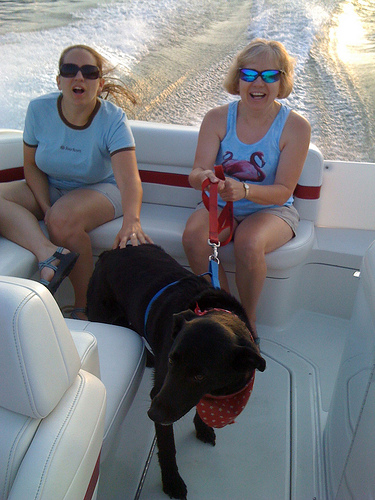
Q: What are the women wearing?
A: Blue shirt.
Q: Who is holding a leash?
A: Woman on right.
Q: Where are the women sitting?
A: In a boat.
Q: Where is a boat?
A: On the water.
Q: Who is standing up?
A: The dog.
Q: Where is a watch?
A: Around woman's wrist.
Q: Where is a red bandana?
A: Around dog's neck.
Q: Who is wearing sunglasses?
A: Both women.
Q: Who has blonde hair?
A: Lady on right.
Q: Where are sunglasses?
A: Over women's eyes.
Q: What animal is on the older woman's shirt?
A: Flamingo.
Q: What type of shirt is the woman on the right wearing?
A: Tank top.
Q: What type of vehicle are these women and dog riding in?
A: Speed boat.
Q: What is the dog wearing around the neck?
A: Bandana.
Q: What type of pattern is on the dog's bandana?
A: Red and white polka dots.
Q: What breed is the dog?
A: Black lab/shepherd mix.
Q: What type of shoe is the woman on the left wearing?
A: Sandals.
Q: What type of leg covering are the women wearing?
A: Short shorts.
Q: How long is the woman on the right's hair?
A: Just below her ears.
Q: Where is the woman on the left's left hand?
A: On the dog.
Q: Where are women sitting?
A: On a boat.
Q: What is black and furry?
A: Dog.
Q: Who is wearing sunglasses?
A: Both women.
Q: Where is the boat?
A: On the water.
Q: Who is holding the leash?
A: Woman on right.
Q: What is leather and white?
A: Boat seats.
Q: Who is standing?
A: The dog.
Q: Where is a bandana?
A: Around dog's neck.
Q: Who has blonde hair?
A: Woman on the right.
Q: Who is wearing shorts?
A: Two women.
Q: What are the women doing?
A: Riding in a boat.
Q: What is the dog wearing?
A: A red handkerchief and a leash.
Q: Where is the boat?
A: On the lake.